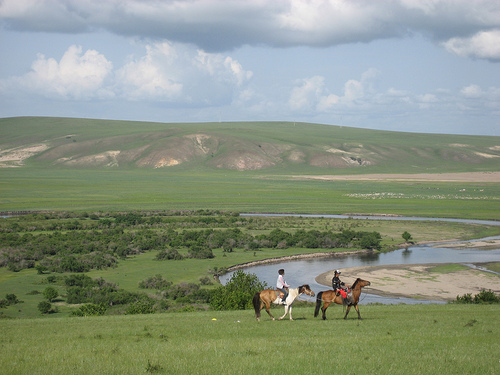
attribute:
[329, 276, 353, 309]
pants — red 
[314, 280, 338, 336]
tail — black 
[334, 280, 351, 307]
pants — red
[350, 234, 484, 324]
ground — brown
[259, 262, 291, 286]
woman — riding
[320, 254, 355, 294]
man — riding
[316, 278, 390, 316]
horse — brown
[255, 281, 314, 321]
horse — brown, white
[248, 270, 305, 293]
rider — moving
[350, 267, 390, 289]
head — raised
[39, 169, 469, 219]
field — vast, green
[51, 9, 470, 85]
sky — cloudy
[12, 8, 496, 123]
sky — cloudy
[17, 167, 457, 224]
area — flat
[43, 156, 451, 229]
area — flat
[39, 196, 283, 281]
trees — forest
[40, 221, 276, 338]
trees — forest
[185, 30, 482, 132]
sky — blue, white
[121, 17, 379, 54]
clouds — thick, puffy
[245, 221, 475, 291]
river — distant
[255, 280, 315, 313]
horse — brown, white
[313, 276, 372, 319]
horse — dark brown, chestnut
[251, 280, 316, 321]
horse — chestnut brown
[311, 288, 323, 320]
tail — long, black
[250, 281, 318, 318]
horse — cream and brown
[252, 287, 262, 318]
tail — long, black